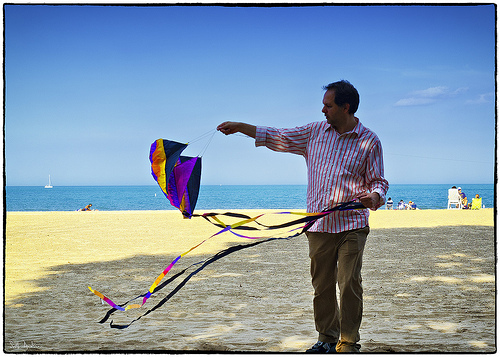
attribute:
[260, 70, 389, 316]
man — standing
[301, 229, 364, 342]
pants — brown, tan, khaki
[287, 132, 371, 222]
shirt — striped, white, orange, stripped, red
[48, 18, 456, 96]
sky — blue, clear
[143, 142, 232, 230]
kite — colorful, multicolored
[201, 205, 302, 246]
tail — long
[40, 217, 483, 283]
ground — sandy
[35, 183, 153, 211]
water — clear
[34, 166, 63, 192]
boat — white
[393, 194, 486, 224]
people — sitting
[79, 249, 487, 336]
sand — tan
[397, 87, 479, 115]
cloud — white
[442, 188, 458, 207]
chair — white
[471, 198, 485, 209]
chair — yellow